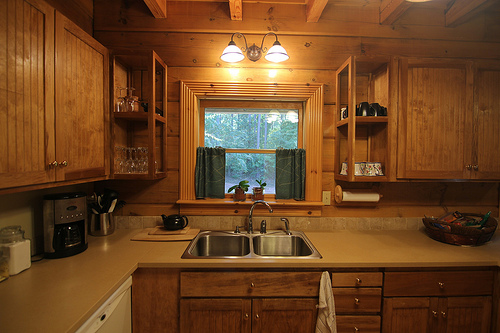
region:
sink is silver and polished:
[163, 191, 343, 290]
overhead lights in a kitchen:
[219, 31, 293, 73]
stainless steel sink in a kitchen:
[172, 198, 323, 268]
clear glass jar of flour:
[0, 223, 42, 277]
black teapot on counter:
[150, 207, 195, 237]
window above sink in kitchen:
[200, 102, 311, 205]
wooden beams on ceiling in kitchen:
[126, 1, 493, 24]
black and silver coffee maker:
[32, 190, 96, 260]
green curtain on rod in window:
[189, 141, 232, 209]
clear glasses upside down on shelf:
[111, 143, 165, 178]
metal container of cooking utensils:
[88, 193, 123, 240]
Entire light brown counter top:
[0, 229, 499, 331]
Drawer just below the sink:
[179, 270, 330, 297]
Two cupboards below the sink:
[178, 298, 318, 331]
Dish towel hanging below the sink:
[313, 270, 337, 331]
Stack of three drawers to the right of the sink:
[331, 273, 386, 331]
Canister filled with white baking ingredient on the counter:
[0, 223, 34, 274]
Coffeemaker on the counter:
[43, 191, 90, 259]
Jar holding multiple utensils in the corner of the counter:
[87, 187, 120, 235]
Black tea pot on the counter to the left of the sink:
[157, 211, 190, 231]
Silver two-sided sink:
[178, 199, 321, 260]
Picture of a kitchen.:
[21, 13, 487, 324]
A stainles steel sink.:
[186, 215, 323, 260]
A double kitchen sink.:
[180, 219, 330, 264]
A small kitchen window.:
[172, 70, 329, 214]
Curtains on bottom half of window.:
[174, 127, 315, 200]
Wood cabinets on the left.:
[7, 51, 112, 185]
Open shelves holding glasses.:
[106, 50, 171, 180]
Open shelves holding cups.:
[327, 58, 394, 190]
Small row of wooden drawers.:
[326, 267, 382, 331]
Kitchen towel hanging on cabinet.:
[305, 259, 349, 331]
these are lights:
[193, 28, 288, 67]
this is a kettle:
[152, 204, 194, 236]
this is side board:
[381, 56, 496, 183]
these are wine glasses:
[114, 140, 152, 181]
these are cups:
[336, 150, 390, 178]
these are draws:
[327, 273, 390, 332]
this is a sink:
[188, 228, 308, 263]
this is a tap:
[237, 198, 292, 236]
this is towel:
[264, 143, 304, 199]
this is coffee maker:
[30, 187, 92, 264]